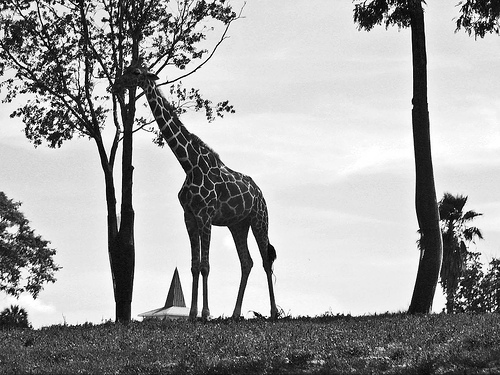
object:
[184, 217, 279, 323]
four legs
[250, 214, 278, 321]
leg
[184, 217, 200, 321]
leg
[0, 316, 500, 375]
hill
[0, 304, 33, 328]
palm bush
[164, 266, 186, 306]
pointy roof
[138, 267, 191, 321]
building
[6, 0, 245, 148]
branches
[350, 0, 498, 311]
tree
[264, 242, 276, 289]
tail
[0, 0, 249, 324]
tall tree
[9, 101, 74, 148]
leaves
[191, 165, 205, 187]
spot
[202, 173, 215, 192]
spot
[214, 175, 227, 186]
spot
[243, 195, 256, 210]
spot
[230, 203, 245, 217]
spot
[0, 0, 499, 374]
zoo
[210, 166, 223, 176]
spots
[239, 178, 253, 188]
spots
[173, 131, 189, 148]
spots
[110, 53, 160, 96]
head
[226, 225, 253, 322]
leg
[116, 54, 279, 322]
giraffe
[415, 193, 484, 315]
palm tree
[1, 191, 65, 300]
tree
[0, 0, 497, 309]
background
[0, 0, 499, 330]
sky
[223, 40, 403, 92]
cloud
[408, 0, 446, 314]
tree trunk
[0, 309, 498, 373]
grassy area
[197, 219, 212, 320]
leg